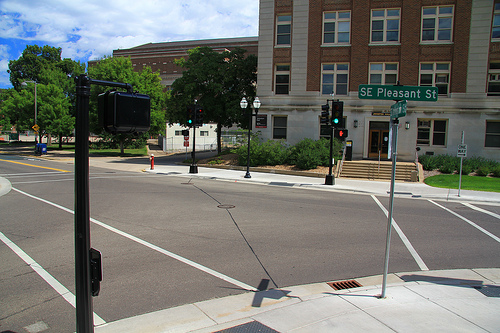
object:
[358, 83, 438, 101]
street sign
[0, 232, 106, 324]
line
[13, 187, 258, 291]
line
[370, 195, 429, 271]
line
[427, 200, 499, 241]
line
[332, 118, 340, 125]
traffic light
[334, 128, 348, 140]
pedestrian signal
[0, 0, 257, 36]
clouds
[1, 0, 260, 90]
sky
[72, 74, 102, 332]
pole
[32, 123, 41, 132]
sign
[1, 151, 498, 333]
road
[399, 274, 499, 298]
shadow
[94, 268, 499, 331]
sidewalk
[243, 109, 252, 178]
lamp post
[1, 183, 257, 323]
crosswalk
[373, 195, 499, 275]
crosswalk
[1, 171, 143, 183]
crosswalk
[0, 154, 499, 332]
intersection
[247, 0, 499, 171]
building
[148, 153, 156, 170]
fire hydrant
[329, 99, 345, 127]
light fixture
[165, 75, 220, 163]
tree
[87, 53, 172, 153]
tree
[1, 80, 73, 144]
tree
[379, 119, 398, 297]
pole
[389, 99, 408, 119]
street sign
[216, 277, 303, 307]
shadow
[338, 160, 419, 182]
steps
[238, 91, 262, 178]
street light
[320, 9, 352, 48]
windows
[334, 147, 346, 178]
railing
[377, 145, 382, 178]
railing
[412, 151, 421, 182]
railing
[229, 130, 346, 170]
bushes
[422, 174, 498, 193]
grass